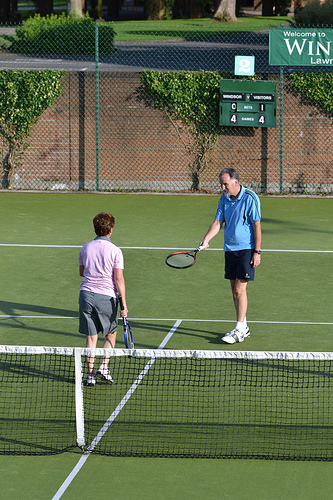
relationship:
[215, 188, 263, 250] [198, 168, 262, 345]
blue shirt on man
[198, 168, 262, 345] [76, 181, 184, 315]
man on court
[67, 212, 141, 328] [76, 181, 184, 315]
woman on court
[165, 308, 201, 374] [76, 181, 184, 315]
line on court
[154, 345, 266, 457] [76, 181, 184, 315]
net on court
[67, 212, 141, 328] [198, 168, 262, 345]
woman near man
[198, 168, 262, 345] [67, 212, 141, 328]
man near woman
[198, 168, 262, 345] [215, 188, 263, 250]
man wearing blue shirt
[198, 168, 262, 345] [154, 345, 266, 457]
man near net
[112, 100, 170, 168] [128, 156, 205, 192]
wall behind fence